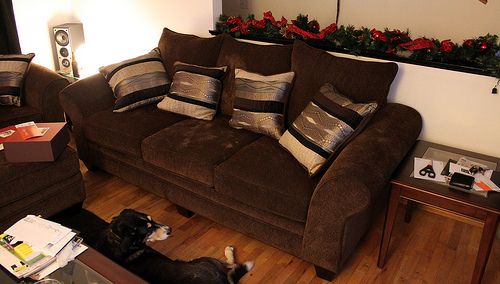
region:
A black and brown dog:
[107, 217, 234, 282]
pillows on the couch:
[168, 55, 343, 149]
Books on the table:
[14, 221, 70, 264]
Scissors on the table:
[424, 148, 436, 188]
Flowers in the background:
[270, 13, 425, 48]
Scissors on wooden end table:
[414, 156, 439, 178]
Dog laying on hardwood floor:
[107, 205, 259, 281]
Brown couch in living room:
[60, 25, 421, 280]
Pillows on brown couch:
[98, 47, 376, 174]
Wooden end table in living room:
[373, 138, 498, 280]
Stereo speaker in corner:
[50, 21, 85, 78]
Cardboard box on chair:
[1, 116, 69, 163]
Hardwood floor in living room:
[68, 115, 498, 282]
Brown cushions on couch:
[86, 90, 328, 227]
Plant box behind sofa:
[211, 12, 498, 79]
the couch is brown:
[65, 22, 422, 266]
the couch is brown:
[78, 10, 398, 265]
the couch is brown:
[58, 23, 385, 270]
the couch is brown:
[74, 35, 374, 275]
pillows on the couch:
[94, 37, 359, 181]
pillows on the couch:
[94, 36, 353, 182]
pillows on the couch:
[107, 42, 359, 178]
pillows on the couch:
[106, 47, 381, 191]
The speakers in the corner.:
[50, 23, 74, 67]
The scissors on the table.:
[415, 155, 435, 177]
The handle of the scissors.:
[419, 155, 439, 179]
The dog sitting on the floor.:
[90, 210, 251, 281]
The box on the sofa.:
[5, 115, 70, 160]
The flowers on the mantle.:
[217, 10, 495, 64]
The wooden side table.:
[377, 136, 498, 281]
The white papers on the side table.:
[409, 153, 489, 193]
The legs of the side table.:
[373, 195, 498, 277]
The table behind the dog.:
[7, 226, 141, 281]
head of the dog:
[97, 213, 167, 243]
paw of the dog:
[217, 244, 237, 261]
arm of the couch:
[338, 156, 387, 212]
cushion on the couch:
[254, 55, 336, 172]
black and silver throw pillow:
[154, 59, 227, 119]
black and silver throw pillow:
[229, 70, 293, 141]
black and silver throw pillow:
[276, 82, 376, 174]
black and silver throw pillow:
[0, 54, 32, 106]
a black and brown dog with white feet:
[93, 208, 254, 283]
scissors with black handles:
[420, 158, 436, 177]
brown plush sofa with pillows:
[61, 26, 422, 281]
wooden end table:
[376, 141, 498, 282]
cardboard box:
[2, 121, 69, 161]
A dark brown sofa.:
[52, 34, 424, 280]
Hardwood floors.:
[65, 112, 498, 282]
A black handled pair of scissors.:
[420, 148, 438, 181]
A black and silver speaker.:
[47, 18, 85, 80]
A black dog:
[96, 200, 252, 282]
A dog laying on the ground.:
[83, 198, 260, 283]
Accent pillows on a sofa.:
[100, 43, 368, 172]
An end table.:
[382, 129, 499, 266]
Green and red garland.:
[212, 8, 496, 76]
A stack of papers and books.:
[3, 211, 85, 281]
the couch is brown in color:
[64, 23, 411, 277]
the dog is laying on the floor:
[95, 211, 255, 282]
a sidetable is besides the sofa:
[376, 139, 498, 279]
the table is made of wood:
[380, 138, 491, 277]